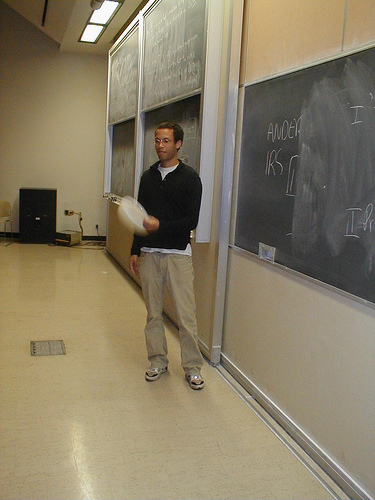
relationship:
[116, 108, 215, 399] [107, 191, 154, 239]
man holding frisbee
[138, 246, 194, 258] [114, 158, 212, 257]
tee shirt hanging out sweater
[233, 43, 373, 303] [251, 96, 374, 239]
blackboard with chalk writing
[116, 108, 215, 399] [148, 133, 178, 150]
man has glasses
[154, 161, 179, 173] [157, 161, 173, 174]
tee shirt neck tee shirt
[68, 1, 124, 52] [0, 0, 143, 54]
lights on ceiling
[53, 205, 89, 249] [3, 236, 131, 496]
projector on floor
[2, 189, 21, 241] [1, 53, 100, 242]
chair against wall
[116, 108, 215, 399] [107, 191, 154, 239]
man carrying frisbee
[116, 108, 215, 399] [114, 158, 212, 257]
man wears shirt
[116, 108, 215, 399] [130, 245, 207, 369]
man wearing pants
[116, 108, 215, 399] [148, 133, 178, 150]
man wears eyeglasses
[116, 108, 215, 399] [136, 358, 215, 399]
man wearing shoes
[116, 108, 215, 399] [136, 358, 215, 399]
man wears shoes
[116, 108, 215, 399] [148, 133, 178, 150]
man wears glasses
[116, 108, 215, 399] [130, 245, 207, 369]
boy wearing pants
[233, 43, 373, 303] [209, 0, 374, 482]
board in wall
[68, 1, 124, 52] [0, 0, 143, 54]
light in ceiling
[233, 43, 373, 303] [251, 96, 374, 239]
blackboard has words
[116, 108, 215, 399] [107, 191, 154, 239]
man holding object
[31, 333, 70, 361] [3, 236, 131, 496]
vent into floor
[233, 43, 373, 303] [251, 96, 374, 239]
board has chalk writing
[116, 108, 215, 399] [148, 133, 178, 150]
man with glasses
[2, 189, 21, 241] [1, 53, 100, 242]
chair in background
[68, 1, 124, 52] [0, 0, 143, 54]
built into ceiling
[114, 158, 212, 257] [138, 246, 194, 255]
sweater over tee shirt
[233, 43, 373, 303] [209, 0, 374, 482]
chalkboard on wall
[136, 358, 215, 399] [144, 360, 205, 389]
boy wearing shoes